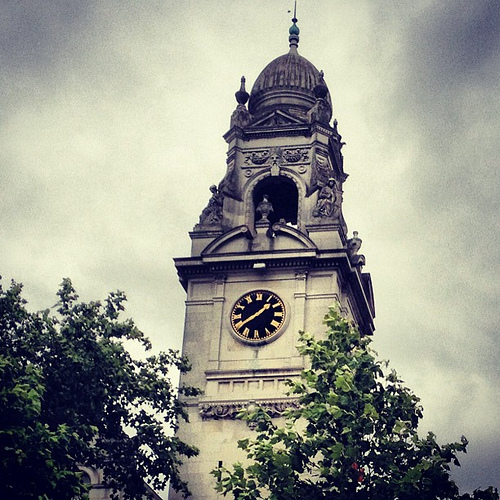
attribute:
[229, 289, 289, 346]
clock — large, black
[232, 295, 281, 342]
numbers — golden, roman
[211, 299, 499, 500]
tree — leafy, green, full, tall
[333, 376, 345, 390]
leaf — green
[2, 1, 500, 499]
sky — cloudy, dark blue, grey, white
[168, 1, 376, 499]
clock tower — large, old, ornate, tall, stone, grey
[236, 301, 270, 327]
hands — gold, golden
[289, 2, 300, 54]
spire — ornate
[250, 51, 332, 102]
dome — rounded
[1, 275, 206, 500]
tree — green